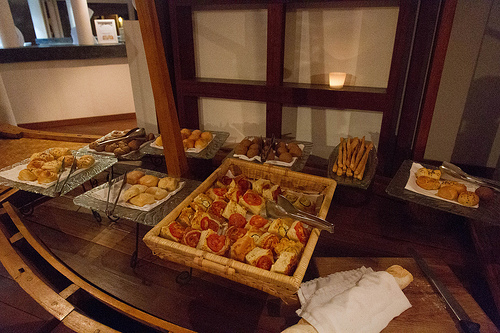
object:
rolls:
[239, 193, 268, 209]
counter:
[5, 29, 132, 59]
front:
[13, 4, 146, 42]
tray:
[330, 132, 384, 190]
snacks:
[334, 139, 373, 180]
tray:
[2, 145, 119, 198]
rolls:
[18, 145, 96, 186]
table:
[4, 129, 500, 332]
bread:
[19, 170, 35, 180]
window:
[184, 4, 390, 167]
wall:
[136, 2, 471, 158]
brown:
[246, 149, 260, 158]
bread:
[235, 145, 247, 154]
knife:
[411, 242, 481, 332]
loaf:
[293, 261, 414, 330]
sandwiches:
[163, 162, 311, 281]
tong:
[266, 188, 336, 237]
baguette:
[124, 184, 141, 199]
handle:
[459, 316, 479, 332]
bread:
[334, 132, 378, 183]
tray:
[147, 153, 341, 303]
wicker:
[148, 157, 340, 293]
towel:
[299, 255, 413, 331]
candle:
[328, 69, 345, 91]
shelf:
[289, 79, 389, 113]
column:
[3, 2, 99, 45]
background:
[4, 4, 139, 118]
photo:
[6, 8, 492, 329]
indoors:
[5, 5, 491, 324]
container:
[0, 142, 118, 225]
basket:
[324, 140, 376, 204]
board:
[314, 254, 497, 332]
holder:
[330, 70, 348, 90]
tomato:
[272, 250, 296, 272]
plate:
[229, 139, 307, 165]